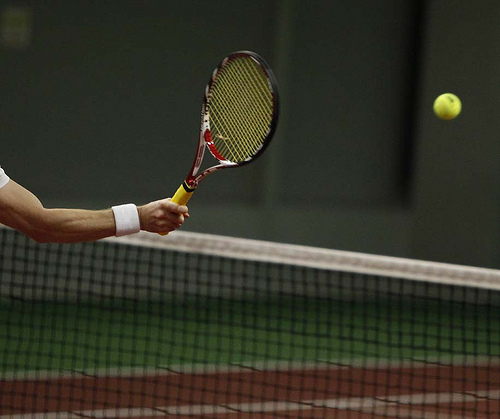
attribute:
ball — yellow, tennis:
[430, 80, 460, 123]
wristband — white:
[114, 194, 141, 241]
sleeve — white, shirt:
[3, 164, 18, 196]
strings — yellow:
[224, 85, 255, 134]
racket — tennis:
[164, 50, 286, 208]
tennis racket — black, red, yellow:
[169, 47, 283, 208]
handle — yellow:
[172, 179, 194, 205]